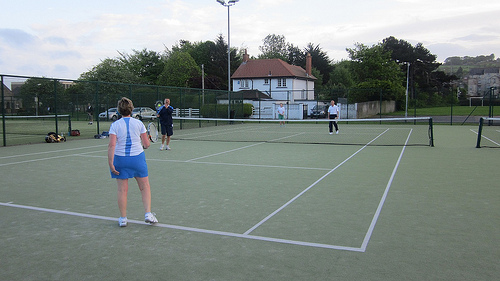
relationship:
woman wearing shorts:
[92, 82, 175, 231] [114, 156, 152, 184]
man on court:
[151, 96, 193, 152] [223, 131, 374, 272]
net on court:
[222, 111, 285, 152] [223, 131, 374, 272]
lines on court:
[313, 161, 343, 197] [223, 131, 374, 272]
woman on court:
[92, 82, 175, 231] [223, 131, 374, 272]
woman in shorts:
[92, 82, 175, 231] [114, 156, 152, 184]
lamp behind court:
[212, 0, 247, 35] [223, 131, 374, 272]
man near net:
[151, 96, 193, 152] [222, 111, 285, 152]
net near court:
[222, 111, 285, 152] [223, 131, 374, 272]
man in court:
[151, 96, 193, 152] [223, 131, 374, 272]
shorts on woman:
[114, 156, 152, 184] [92, 82, 175, 231]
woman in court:
[92, 82, 175, 231] [223, 131, 374, 272]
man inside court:
[151, 96, 193, 152] [223, 131, 374, 272]